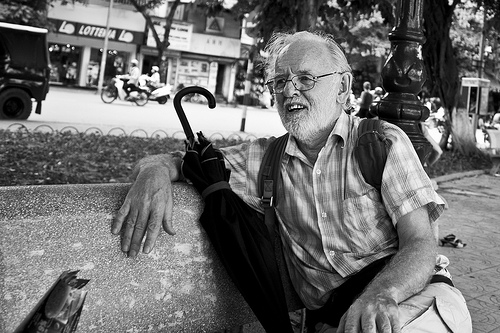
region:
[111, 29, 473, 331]
Man sitting on bench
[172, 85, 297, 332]
Umbrella next to man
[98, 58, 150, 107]
Person riding a motocycle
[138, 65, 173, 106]
Person riding a motorcycle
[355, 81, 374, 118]
Person in the background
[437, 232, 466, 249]
Birds standing on sidewalk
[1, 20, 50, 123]
Back end of jeep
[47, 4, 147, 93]
Store on side of road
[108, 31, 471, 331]
Man wearing a plaid shirt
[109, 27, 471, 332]
Older man with balding hair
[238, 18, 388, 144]
head of a man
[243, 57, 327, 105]
glasses on the man's face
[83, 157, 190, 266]
hand of the man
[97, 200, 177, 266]
fingers on the man's hand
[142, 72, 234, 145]
handle of the umbrella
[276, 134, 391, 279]
buttons on the shirt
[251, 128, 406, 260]
checkered shirt on man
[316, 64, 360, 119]
ear of the man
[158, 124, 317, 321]
umbrella next to man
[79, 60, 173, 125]
people on bikes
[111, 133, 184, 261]
the mans arm on the back of the bench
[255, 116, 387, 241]
the black straps over the back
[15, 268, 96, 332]
the black plastic bag on the bench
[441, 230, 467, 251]
the sandal on the sidewalk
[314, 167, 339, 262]
the white buttons on the shirt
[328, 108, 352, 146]
the collar on the shirt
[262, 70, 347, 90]
the glasses on the mans face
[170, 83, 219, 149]
the handle of the umbrella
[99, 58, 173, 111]
the motorcycleists on the road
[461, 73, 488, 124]
the booth on the sidewalk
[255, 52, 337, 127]
man is wearing eyeglasses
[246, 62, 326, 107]
man is wearing eyeglasses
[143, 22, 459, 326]
man sitting on the bench